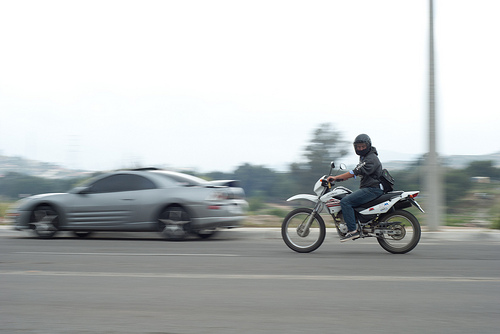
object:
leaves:
[250, 169, 256, 172]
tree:
[290, 122, 354, 196]